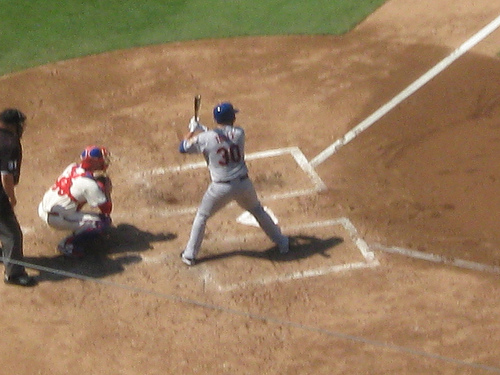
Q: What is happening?
A: A baseball game.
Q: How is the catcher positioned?
A: Crouching.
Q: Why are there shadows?
A: It is sunny.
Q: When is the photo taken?
A: Daytime.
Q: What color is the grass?
A: Green.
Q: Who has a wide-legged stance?
A: The batter.